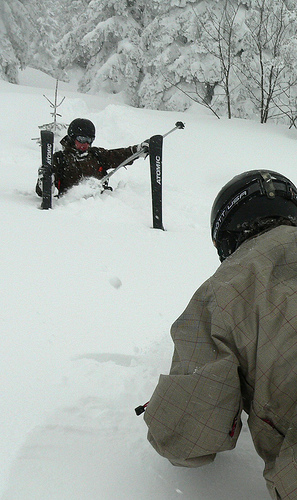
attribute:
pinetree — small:
[30, 78, 66, 139]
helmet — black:
[64, 116, 102, 151]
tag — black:
[131, 403, 146, 417]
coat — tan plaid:
[146, 232, 295, 496]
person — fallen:
[33, 114, 153, 200]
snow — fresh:
[51, 373, 122, 480]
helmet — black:
[207, 166, 294, 264]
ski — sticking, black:
[145, 132, 170, 232]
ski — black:
[39, 130, 55, 211]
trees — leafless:
[180, 4, 290, 111]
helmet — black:
[207, 168, 295, 241]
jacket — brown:
[133, 241, 292, 498]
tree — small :
[41, 71, 70, 146]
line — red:
[227, 274, 242, 295]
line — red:
[237, 307, 253, 324]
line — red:
[195, 299, 209, 322]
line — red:
[190, 393, 214, 405]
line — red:
[163, 399, 183, 413]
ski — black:
[147, 133, 166, 231]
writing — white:
[154, 154, 161, 185]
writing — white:
[46, 141, 52, 165]